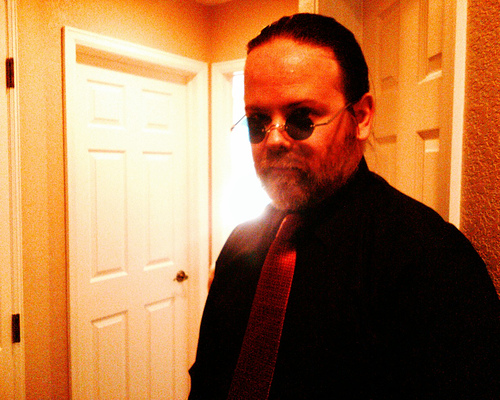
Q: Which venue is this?
A: This is a hallway.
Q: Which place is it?
A: It is a hallway.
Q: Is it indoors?
A: Yes, it is indoors.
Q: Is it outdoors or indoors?
A: It is indoors.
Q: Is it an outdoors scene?
A: No, it is indoors.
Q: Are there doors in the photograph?
A: Yes, there is a door.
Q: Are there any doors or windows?
A: Yes, there is a door.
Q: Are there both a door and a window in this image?
A: No, there is a door but no windows.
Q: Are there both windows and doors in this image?
A: No, there is a door but no windows.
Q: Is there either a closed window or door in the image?
A: Yes, there is a closed door.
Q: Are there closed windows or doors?
A: Yes, there is a closed door.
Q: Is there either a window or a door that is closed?
A: Yes, the door is closed.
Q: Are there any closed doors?
A: Yes, there is a closed door.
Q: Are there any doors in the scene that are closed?
A: Yes, there is a door that is closed.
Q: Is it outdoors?
A: No, it is indoors.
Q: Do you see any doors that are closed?
A: Yes, there is a door that is closed.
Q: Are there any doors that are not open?
A: Yes, there is an closed door.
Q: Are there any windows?
A: No, there are no windows.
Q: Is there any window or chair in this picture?
A: No, there are no windows or chairs.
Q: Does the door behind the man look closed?
A: Yes, the door is closed.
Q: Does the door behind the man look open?
A: No, the door is closed.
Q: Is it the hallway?
A: Yes, it is the hallway.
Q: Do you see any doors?
A: Yes, there is a door.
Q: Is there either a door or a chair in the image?
A: Yes, there is a door.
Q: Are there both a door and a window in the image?
A: No, there is a door but no windows.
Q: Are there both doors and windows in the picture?
A: No, there is a door but no windows.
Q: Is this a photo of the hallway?
A: Yes, it is showing the hallway.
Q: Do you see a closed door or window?
A: Yes, there is a closed door.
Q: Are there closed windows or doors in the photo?
A: Yes, there is a closed door.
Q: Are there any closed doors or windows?
A: Yes, there is a closed door.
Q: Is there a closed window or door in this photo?
A: Yes, there is a closed door.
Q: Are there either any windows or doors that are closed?
A: Yes, the door is closed.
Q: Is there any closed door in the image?
A: Yes, there is a closed door.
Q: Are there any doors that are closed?
A: Yes, there is a door that is closed.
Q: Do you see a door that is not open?
A: Yes, there is an closed door.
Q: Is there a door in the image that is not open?
A: Yes, there is an closed door.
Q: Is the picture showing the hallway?
A: Yes, it is showing the hallway.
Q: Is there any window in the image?
A: No, there are no windows.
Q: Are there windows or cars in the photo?
A: No, there are no windows or cars.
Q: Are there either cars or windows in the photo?
A: No, there are no windows or cars.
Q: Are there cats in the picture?
A: No, there are no cats.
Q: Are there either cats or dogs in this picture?
A: No, there are no cats or dogs.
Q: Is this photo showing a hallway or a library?
A: It is showing a hallway.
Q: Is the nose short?
A: Yes, the nose is short.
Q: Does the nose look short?
A: Yes, the nose is short.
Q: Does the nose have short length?
A: Yes, the nose is short.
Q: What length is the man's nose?
A: The nose is short.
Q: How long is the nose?
A: The nose is short.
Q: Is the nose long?
A: No, the nose is short.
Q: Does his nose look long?
A: No, the nose is short.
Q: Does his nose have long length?
A: No, the nose is short.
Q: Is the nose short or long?
A: The nose is short.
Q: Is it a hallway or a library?
A: It is a hallway.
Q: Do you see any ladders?
A: No, there are no ladders.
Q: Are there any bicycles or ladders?
A: No, there are no ladders or bicycles.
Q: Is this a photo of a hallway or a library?
A: It is showing a hallway.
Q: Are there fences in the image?
A: No, there are no fences.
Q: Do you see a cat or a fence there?
A: No, there are no fences or cats.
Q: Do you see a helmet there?
A: No, there are no helmets.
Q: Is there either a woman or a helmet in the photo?
A: No, there are no helmets or women.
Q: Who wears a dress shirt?
A: The man wears a dress shirt.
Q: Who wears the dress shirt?
A: The man wears a dress shirt.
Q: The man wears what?
A: The man wears a dress shirt.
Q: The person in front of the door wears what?
A: The man wears a dress shirt.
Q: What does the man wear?
A: The man wears a dress shirt.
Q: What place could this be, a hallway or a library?
A: It is a hallway.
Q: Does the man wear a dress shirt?
A: Yes, the man wears a dress shirt.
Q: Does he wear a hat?
A: No, the man wears a dress shirt.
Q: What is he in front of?
A: The man is in front of the door.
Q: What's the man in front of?
A: The man is in front of the door.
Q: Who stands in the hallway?
A: The man stands in the hallway.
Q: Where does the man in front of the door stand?
A: The man stands in the hallway.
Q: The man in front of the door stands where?
A: The man stands in the hallway.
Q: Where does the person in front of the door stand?
A: The man stands in the hallway.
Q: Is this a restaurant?
A: No, it is a hallway.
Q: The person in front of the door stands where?
A: The man stands in the hallway.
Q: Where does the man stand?
A: The man stands in the hallway.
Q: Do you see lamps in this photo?
A: No, there are no lamps.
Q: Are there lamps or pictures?
A: No, there are no lamps or pictures.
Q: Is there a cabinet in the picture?
A: No, there are no cabinets.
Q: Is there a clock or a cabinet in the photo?
A: No, there are no cabinets or clocks.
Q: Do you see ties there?
A: Yes, there is a tie.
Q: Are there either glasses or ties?
A: Yes, there is a tie.